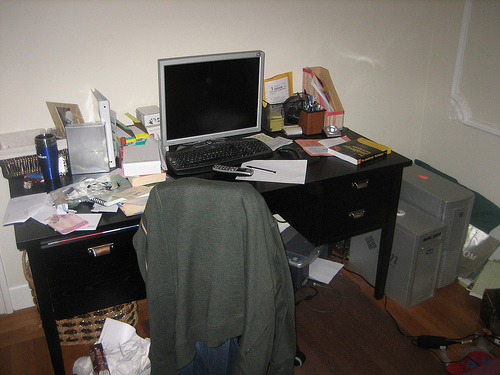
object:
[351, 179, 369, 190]
handle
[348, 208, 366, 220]
handle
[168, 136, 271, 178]
keyboard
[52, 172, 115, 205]
phone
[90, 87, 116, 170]
binder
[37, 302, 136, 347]
basket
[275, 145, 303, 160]
mouse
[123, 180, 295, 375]
jacket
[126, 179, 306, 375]
chair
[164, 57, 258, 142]
screen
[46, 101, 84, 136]
frame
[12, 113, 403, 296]
desk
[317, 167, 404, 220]
drawer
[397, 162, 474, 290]
computer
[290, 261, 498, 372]
floor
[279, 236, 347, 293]
printer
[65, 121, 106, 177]
box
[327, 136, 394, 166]
magazine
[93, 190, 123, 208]
notebook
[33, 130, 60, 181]
container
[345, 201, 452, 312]
tower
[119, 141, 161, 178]
book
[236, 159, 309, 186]
paper